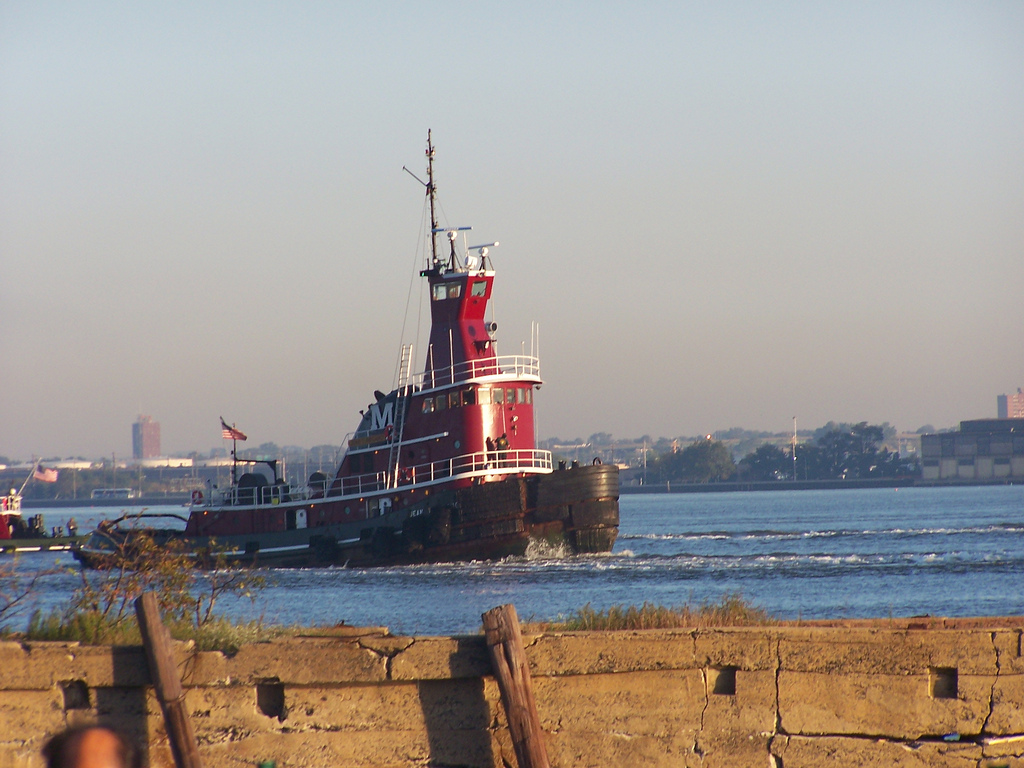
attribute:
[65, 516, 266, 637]
bush — bare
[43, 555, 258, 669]
tree — green